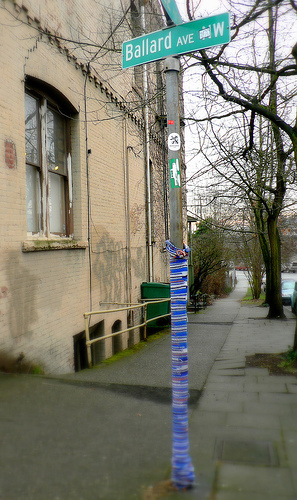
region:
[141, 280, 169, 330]
Green garbage bin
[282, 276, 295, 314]
Cars parked on side of road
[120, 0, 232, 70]
Green street signs with white writing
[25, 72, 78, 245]
Window on side of brick building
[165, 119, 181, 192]
Stickers on pole for street signs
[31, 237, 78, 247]
Moss growing on exterior window ledge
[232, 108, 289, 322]
Row of trees on sidewalk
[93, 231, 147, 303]
Graffiti on side of brick building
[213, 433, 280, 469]
Square metal plate in sidewalk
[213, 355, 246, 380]
Raised blocks in sidewalk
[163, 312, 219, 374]
this is a long pole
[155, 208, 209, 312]
the pole is metal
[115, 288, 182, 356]
the pole is covered in blue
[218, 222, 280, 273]
This is an old tree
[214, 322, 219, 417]
This is a sidewalk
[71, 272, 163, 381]
This is a small fence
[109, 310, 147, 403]
The fence is made of metal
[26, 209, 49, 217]
This is a window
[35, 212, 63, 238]
This is a window sill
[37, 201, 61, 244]
The window is chipped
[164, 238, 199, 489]
blue cloth wrapped around metal sign pole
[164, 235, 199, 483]
bottom of sign has wrapping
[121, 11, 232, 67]
bottom sign is readable from the position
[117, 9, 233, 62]
sign reads "Ballard ave"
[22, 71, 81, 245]
large window pane in side of building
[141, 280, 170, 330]
green plastic trash bin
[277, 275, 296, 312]
cars parked on the side of the street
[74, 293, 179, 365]
yellow metal railing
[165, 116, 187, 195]
stickers and labels on street pole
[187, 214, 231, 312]
small trees and bushes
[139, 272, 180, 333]
the trashbin is green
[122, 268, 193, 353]
the trashbin is green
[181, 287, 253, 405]
the sidewalk is paved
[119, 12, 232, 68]
green and white sign indicating Ballard street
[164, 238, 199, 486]
blue knit stocking on metal pole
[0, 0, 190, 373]
cream brick building on sidewalk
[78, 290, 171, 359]
cream metal railing leading to basement entrance of building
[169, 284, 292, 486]
sidewalk lined in trees made of cement pavers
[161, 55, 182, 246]
metal pole attached to green street signs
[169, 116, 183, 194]
white and green stickers on street pole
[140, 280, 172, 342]
green plastic garbage cans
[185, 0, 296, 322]
very tall tree planted on sidewalk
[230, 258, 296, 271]
cars parked in distance at end of road